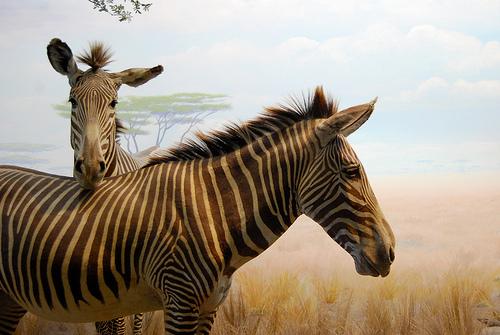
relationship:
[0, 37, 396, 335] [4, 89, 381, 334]
animals looking over zebra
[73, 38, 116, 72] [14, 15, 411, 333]
hair on zebra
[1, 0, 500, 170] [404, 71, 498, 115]
sky with cloud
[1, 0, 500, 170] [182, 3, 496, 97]
sky with cloud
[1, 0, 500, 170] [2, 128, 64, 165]
sky with cloud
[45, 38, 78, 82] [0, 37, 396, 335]
ear of a animals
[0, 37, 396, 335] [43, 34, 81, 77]
animals with ear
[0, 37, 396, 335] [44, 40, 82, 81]
animals has ear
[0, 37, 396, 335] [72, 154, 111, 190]
animals has nose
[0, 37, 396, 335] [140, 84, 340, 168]
animals has hair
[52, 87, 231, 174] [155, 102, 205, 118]
tree has leaves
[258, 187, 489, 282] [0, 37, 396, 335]
pasture behind animals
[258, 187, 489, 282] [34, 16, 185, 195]
pasture behind zebra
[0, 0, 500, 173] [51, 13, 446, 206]
cloud in sky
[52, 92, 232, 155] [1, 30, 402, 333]
tree behind zebras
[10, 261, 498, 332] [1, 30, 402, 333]
wheat behind zebras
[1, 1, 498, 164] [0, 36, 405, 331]
sky behind zebra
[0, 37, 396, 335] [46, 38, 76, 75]
animals has ear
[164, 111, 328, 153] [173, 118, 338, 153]
hair on spine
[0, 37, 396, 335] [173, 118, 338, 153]
animals has spine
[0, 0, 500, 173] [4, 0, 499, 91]
cloud in sky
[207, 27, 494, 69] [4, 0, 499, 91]
cloud in sky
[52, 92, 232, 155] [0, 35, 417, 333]
tree behind animals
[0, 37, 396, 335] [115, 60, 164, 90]
animals has ear